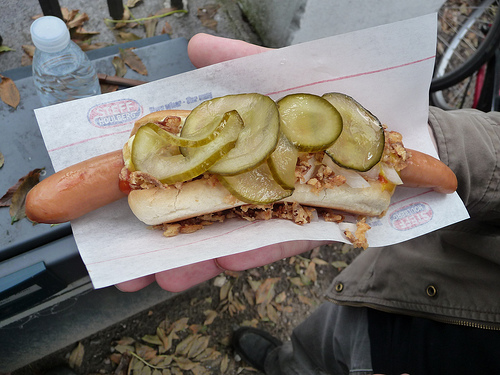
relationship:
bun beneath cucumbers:
[128, 108, 399, 227] [189, 91, 381, 175]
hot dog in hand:
[25, 147, 459, 224] [106, 29, 437, 296]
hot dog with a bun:
[21, 149, 456, 223] [124, 117, 396, 214]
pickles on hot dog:
[127, 91, 384, 201] [21, 149, 456, 223]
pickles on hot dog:
[219, 132, 298, 207] [21, 149, 456, 223]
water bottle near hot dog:
[28, 16, 102, 107] [25, 147, 459, 224]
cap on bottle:
[32, 19, 77, 51] [32, 28, 97, 104]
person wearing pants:
[96, 31, 498, 373] [264, 300, 373, 374]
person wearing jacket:
[96, 31, 498, 373] [322, 107, 498, 333]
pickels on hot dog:
[124, 87, 388, 204] [26, 118, 459, 226]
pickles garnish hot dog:
[127, 91, 384, 201] [25, 147, 459, 224]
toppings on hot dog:
[144, 103, 407, 230] [25, 142, 452, 225]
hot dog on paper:
[25, 147, 459, 224] [27, 2, 475, 294]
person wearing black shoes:
[96, 31, 498, 373] [232, 321, 294, 370]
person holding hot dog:
[113, 31, 500, 374] [63, 108, 496, 219]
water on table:
[31, 15, 102, 104] [3, 35, 210, 373]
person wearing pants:
[113, 31, 500, 374] [228, 298, 370, 373]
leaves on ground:
[62, 242, 362, 374] [0, 0, 498, 367]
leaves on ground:
[192, 334, 208, 360] [0, 0, 498, 367]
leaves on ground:
[116, 43, 153, 78] [0, 0, 498, 367]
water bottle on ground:
[24, 12, 102, 108] [0, 0, 498, 367]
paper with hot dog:
[95, 96, 205, 247] [25, 147, 459, 224]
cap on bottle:
[30, 16, 70, 54] [24, 13, 105, 116]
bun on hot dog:
[128, 177, 396, 221] [25, 142, 452, 225]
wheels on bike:
[421, 11, 498, 120] [431, 0, 498, 114]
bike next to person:
[431, 0, 498, 114] [185, 0, 497, 371]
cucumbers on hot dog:
[133, 92, 384, 203] [23, 90, 460, 223]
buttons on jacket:
[331, 279, 441, 300] [322, 107, 498, 333]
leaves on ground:
[0, 5, 282, 108] [0, 0, 498, 367]